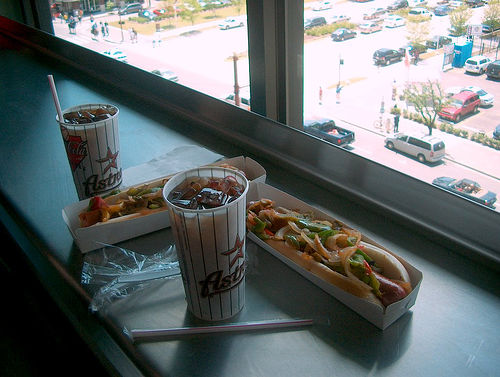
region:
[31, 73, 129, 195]
soda with ice and straw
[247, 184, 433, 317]
Hot dog with peppers and onions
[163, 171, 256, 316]
cup with Astros logo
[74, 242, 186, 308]
cellophane from plastic utensil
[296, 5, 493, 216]
large glass window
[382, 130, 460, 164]
white minivan parked on street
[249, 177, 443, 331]
hot dog in white cardboard holder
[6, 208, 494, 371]
blue counter to eat concessions on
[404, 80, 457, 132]
tree planted in sidewalk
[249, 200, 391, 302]
red and green peppers on hot dog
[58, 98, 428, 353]
Food is on counter.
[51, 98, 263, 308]
Two cups of drinks are on counter.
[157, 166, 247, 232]
Ice cubes are floating in drinks.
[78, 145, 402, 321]
Two hot dogs are in the picture.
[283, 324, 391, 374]
Counter is blue color.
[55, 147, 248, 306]
Cup is white color.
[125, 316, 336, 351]
Straw is white color.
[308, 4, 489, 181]
Cars are on road.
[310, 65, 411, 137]
people are walking in road.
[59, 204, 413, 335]
Box is white color.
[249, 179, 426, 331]
Chicago style hot dog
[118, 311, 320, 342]
Wrapped straw on a countertop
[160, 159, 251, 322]
Iced cold beverage in Astros cup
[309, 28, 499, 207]
Cars in parking lot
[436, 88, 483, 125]
Parked red SUV vehicle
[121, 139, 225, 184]
Paper napkin on a counter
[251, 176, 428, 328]
Footlong hot dog in disposable paper tray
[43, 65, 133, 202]
Cold beverage in paper cup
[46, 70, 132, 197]
Straw in iced beverage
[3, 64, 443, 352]
Concession snacks on a countertop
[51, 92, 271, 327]
two paper cups with soft drink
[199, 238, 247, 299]
name of baseball team on cup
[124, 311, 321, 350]
straw in plastic on counter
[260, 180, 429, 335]
hotdog in cardboard conatiner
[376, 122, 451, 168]
minivan on street below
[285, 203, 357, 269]
onions and peppers on hotdog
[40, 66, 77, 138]
straw inside paper cup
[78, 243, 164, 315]
empty plastic bag on counter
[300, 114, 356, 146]
pickup truck on street below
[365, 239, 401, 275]
top edge of hotdog bun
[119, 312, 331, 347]
straw wrapped in plastic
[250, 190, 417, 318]
hot dog in a bread bun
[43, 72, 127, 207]
soda with a drinking straw in it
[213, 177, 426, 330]
cardboard paper rectangular food holder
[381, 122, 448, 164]
white minivan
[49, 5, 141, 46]
people walking on the street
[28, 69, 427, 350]
two meals and two drinks on a counter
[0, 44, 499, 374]
counter facing street below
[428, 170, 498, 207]
convertible car with the top down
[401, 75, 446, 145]
tree growing in the middle of a sidewalk